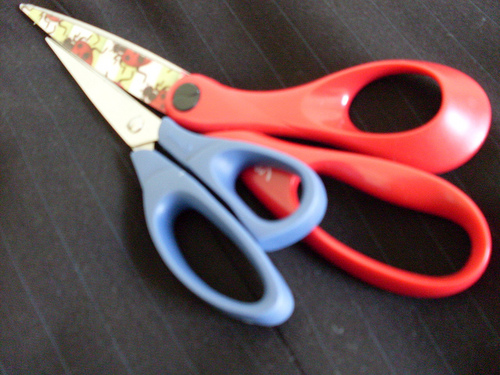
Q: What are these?
A: Scissors.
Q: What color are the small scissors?
A: Blue.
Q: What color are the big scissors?
A: Red.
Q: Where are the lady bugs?
A: On the red scissor's blades.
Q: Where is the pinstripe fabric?
A: Beneath the scissors.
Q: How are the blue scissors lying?
A: Atop the red scissors.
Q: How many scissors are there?
A: Two.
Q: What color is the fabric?
A: Black.